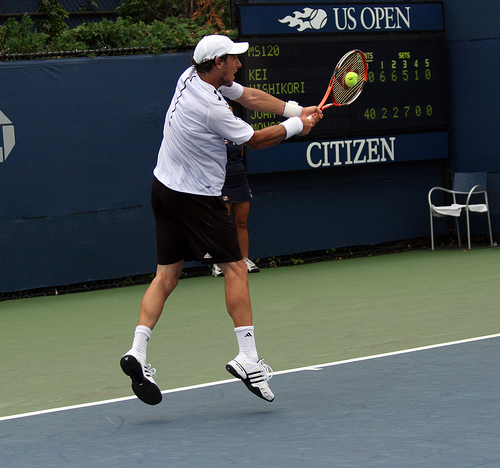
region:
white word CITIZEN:
[296, 125, 398, 172]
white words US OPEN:
[325, 8, 412, 33]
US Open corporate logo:
[279, 0, 415, 34]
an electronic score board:
[236, 36, 450, 135]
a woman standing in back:
[229, 69, 269, 275]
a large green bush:
[11, 12, 206, 57]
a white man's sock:
[231, 318, 258, 359]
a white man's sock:
[122, 316, 152, 365]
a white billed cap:
[189, 32, 252, 67]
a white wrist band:
[278, 114, 303, 135]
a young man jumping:
[114, 30, 322, 409]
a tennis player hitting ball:
[119, 30, 369, 409]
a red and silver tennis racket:
[304, 47, 372, 116]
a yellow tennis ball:
[345, 71, 357, 85]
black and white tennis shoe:
[220, 347, 284, 408]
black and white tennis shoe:
[116, 348, 161, 403]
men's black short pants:
[141, 169, 241, 271]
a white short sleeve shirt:
[146, 60, 258, 191]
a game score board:
[231, 2, 451, 171]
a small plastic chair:
[424, 170, 492, 255]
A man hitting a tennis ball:
[108, 26, 373, 288]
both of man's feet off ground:
[84, 228, 301, 434]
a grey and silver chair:
[423, 159, 494, 255]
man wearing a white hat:
[169, 23, 259, 85]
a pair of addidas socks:
[109, 311, 273, 372]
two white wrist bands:
[274, 90, 315, 147]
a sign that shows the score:
[226, 10, 465, 183]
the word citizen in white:
[292, 133, 416, 173]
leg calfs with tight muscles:
[112, 277, 272, 339]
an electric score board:
[228, 30, 468, 142]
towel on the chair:
[406, 168, 497, 244]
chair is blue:
[433, 158, 497, 256]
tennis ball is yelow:
[328, 59, 364, 100]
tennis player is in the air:
[90, 293, 351, 458]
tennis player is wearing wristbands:
[273, 91, 325, 174]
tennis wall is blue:
[45, 62, 163, 250]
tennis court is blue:
[303, 361, 450, 448]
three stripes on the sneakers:
[217, 368, 296, 397]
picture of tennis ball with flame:
[280, 0, 330, 32]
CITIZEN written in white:
[304, 137, 423, 175]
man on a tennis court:
[1, 6, 498, 466]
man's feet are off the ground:
[110, 305, 291, 419]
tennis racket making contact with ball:
[331, 48, 370, 105]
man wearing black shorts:
[143, 183, 247, 272]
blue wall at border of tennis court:
[5, 57, 499, 329]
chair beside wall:
[415, 129, 495, 256]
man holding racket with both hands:
[293, 42, 380, 144]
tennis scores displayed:
[231, 5, 458, 160]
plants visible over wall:
[3, 3, 247, 89]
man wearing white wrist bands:
[271, 97, 313, 140]